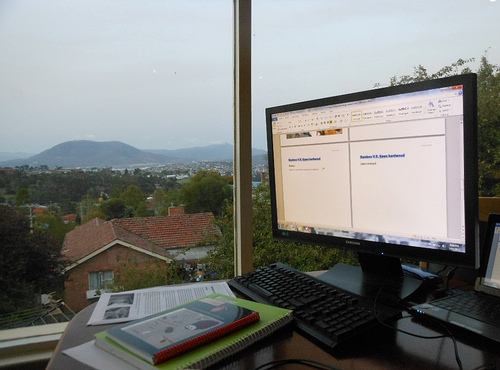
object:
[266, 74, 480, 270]
screen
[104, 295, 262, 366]
book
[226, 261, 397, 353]
keyboard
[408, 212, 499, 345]
laptop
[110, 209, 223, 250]
roof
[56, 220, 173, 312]
house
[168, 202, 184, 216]
chimney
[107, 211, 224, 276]
houses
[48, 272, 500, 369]
desk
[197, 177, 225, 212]
tree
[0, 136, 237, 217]
distance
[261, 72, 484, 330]
computer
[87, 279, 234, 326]
paper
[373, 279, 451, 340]
wire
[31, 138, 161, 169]
mountain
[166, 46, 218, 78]
clouds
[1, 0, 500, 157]
sky